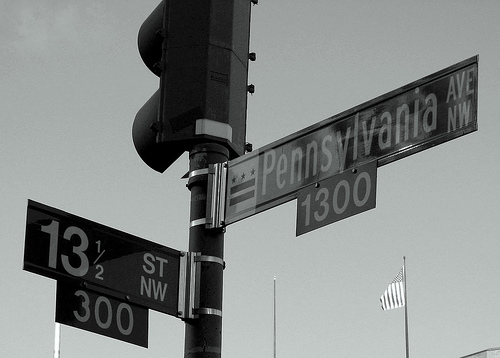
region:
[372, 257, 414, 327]
American flag on a flag pole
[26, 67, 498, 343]
Instersection of 13-1/2 St and Pennsylvania Ave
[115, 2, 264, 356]
Traffic light on a black pole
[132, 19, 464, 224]
Traffic light above street sign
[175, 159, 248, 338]
Metal brackets holding street signs to pole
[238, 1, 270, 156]
Bolts holding traffic light to pole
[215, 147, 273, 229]
Stars and stripes graphic on street sign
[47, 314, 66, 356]
White pole behind street sign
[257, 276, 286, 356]
Empty flag pole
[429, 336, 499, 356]
Building roof near street intersection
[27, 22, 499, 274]
twoo street signs on a pole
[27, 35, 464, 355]
two signs on a pole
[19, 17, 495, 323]
two street signs under a light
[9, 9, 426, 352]
two signs under a light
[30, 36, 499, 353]
two street signs under a traffic light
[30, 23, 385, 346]
two signs under a traffic light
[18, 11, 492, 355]
street signs under a light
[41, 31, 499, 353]
street signs under a traffic light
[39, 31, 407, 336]
signs under a light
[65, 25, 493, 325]
signs under a traffic light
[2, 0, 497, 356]
the picture is black and white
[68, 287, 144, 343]
the sign says 300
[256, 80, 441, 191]
the sign says pennsylvania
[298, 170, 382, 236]
the sign says 1300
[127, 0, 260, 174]
the light is above the signs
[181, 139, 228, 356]
the pole is black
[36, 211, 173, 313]
the sign says 13 1/2 st nw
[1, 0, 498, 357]
the sky is grey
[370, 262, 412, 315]
the flag is American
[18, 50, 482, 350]
the signs are facing different directions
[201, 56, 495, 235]
The sign is rectangular.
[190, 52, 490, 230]
The sign has lettering.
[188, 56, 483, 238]
The lettering is printed.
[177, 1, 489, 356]
Sign is attached to pole.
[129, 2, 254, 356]
Streetlight attached to pole.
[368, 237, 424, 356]
Flag flying in background.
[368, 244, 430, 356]
The flag is a U.S. flag.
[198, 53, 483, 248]
Smaller sign attached to larger one.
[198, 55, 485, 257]
Smaller sign has numbers.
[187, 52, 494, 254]
Smaller sign is rectangular.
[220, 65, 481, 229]
a street name sign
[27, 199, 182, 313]
a street name sign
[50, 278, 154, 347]
a street number sign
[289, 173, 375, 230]
a street number sign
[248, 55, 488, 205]
printed name Pennsylvania AVE NW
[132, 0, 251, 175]
an electric traffic street signal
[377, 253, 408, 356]
a waving American flag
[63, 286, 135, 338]
printed number 300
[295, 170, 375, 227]
printed number 1300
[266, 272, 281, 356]
a tall metal pole